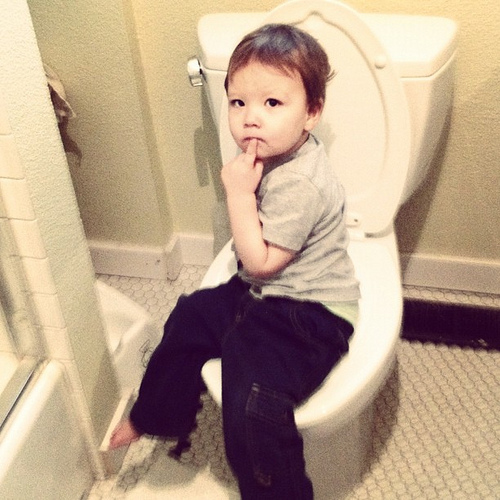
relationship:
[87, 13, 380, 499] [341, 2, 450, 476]
boy seat on top toilet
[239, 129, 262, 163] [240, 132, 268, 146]
finger in mouth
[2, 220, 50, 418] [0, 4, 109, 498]
edge of a bathtub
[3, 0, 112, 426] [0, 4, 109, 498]
tile lining a shower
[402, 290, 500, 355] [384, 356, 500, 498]
vent in floor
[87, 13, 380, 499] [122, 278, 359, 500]
boy has blue jeans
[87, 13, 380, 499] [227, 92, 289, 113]
boy has eye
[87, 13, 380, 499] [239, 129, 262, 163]
boy has a finger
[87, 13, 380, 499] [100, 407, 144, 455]
boy has a foot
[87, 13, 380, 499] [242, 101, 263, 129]
boy has a nose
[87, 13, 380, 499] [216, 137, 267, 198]
boy has a hand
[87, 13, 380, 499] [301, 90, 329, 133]
boy has an ear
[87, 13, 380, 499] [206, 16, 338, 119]
boy has hair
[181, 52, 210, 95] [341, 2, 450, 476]
handle of toilet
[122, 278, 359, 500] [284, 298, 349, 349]
pants has pocket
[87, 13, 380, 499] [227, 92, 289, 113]
boy has eyes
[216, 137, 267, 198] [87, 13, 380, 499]
hand of boy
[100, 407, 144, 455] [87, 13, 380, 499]
foot of boy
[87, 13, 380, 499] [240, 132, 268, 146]
boy has a mouth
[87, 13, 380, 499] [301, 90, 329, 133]
boy has ear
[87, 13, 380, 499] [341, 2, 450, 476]
child sitting on toilet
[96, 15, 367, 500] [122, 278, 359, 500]
children has pair of jeans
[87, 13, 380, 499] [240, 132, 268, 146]
child touching h lips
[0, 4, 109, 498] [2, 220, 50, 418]
bathtub seen corner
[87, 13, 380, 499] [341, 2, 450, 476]
kid on toilet toilet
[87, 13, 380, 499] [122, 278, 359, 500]
kid has pants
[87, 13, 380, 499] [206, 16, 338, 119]
kid has brown hair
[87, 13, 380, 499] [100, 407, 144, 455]
child has bare feet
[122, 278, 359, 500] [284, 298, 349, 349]
pants have pocket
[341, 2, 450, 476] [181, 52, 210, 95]
toilet has handle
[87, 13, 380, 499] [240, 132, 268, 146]
kid has finger in mouth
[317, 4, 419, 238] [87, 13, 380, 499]
toilet seat behind kid